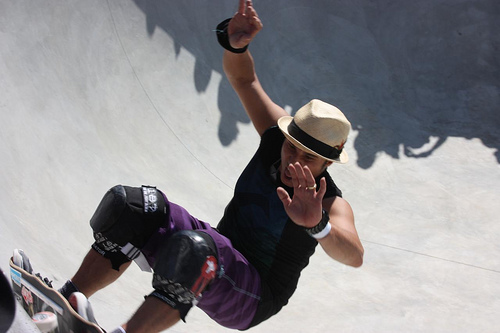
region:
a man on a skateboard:
[2, 5, 370, 331]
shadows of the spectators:
[146, 32, 499, 168]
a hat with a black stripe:
[276, 95, 361, 170]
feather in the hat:
[333, 136, 348, 152]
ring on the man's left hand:
[303, 180, 319, 192]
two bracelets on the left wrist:
[296, 204, 335, 241]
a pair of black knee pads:
[78, 175, 228, 295]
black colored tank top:
[210, 122, 343, 312]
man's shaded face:
[275, 132, 332, 191]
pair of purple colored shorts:
[149, 186, 266, 331]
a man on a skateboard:
[15, 5, 427, 324]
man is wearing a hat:
[270, 85, 365, 175]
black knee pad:
[92, 181, 166, 250]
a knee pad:
[143, 218, 223, 312]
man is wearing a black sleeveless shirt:
[225, 119, 350, 319]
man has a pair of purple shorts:
[142, 192, 279, 330]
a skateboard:
[5, 241, 113, 327]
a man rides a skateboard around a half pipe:
[6, 6, 439, 328]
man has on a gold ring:
[305, 181, 320, 193]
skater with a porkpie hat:
[275, 88, 360, 173]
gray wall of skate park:
[16, 13, 122, 155]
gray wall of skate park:
[71, 70, 192, 185]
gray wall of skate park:
[367, 182, 483, 318]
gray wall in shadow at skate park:
[302, 14, 497, 91]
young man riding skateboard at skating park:
[18, 9, 375, 329]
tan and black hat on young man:
[276, 90, 366, 166]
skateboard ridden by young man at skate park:
[6, 250, 133, 328]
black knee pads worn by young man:
[71, 177, 222, 302]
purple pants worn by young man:
[150, 184, 273, 325]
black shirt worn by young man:
[198, 103, 340, 280]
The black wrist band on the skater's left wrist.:
[215, 18, 252, 58]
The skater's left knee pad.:
[87, 178, 169, 237]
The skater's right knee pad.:
[158, 217, 215, 302]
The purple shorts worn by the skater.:
[166, 203, 258, 322]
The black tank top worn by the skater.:
[224, 127, 308, 283]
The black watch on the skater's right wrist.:
[306, 206, 330, 239]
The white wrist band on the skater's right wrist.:
[312, 218, 332, 245]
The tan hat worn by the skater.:
[268, 78, 353, 151]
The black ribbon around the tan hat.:
[291, 118, 348, 157]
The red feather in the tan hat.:
[332, 138, 349, 153]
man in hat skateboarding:
[45, 5, 357, 331]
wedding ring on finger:
[303, 180, 318, 193]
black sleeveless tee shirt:
[237, 126, 329, 331]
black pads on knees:
[87, 184, 207, 279]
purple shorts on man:
[165, 202, 265, 326]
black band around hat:
[288, 117, 342, 162]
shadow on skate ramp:
[385, 120, 464, 171]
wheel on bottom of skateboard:
[27, 306, 64, 331]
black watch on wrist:
[302, 209, 336, 236]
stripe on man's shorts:
[222, 272, 255, 297]